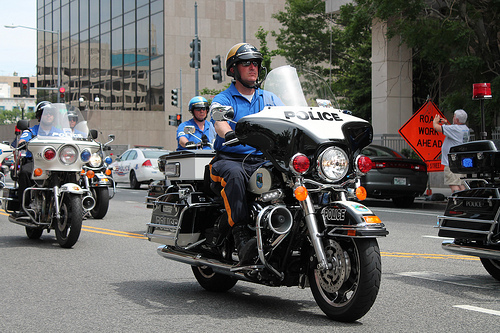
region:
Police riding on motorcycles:
[18, 33, 455, 315]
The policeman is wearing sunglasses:
[214, 30, 408, 330]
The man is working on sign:
[347, 60, 492, 187]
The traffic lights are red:
[16, 54, 98, 148]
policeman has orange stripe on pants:
[154, 41, 403, 262]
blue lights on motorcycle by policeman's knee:
[138, 58, 369, 265]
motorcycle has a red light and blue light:
[9, 87, 130, 254]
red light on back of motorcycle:
[438, 42, 497, 195]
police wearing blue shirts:
[176, 30, 345, 187]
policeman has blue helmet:
[161, 61, 213, 153]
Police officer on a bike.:
[160, 12, 341, 217]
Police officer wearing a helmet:
[153, 47, 374, 281]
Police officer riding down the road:
[124, 15, 433, 287]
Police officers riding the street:
[61, 23, 387, 245]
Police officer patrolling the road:
[100, 6, 399, 323]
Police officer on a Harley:
[93, 88, 428, 282]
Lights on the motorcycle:
[200, 107, 415, 214]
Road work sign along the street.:
[406, 96, 448, 178]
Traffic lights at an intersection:
[18, 65, 153, 114]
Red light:
[25, 55, 82, 99]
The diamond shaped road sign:
[401, 97, 452, 160]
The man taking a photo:
[433, 106, 470, 200]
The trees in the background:
[252, 3, 497, 134]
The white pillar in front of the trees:
[366, 13, 420, 154]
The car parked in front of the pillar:
[350, 136, 427, 208]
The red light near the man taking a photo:
[464, 74, 496, 108]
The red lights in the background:
[19, 73, 185, 124]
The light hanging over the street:
[4, 19, 66, 40]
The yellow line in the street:
[73, 212, 490, 266]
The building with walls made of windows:
[31, 0, 172, 118]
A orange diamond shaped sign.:
[392, 93, 465, 169]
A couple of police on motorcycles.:
[134, 24, 428, 323]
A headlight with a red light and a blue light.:
[38, 135, 95, 173]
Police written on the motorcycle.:
[243, 2, 375, 194]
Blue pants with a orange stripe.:
[198, 142, 263, 249]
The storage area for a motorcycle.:
[156, 126, 245, 288]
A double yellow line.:
[383, 231, 479, 281]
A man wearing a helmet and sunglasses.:
[218, 39, 277, 84]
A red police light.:
[460, 73, 496, 130]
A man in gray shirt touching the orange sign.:
[416, 95, 481, 167]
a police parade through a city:
[2, 19, 485, 307]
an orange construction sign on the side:
[386, 101, 446, 161]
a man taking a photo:
[431, 108, 468, 199]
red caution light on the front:
[290, 149, 313, 172]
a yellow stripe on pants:
[207, 164, 237, 226]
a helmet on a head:
[213, 41, 275, 85]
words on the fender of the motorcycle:
[323, 206, 354, 220]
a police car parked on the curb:
[123, 141, 160, 185]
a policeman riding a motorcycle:
[8, 102, 100, 237]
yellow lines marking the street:
[389, 242, 444, 262]